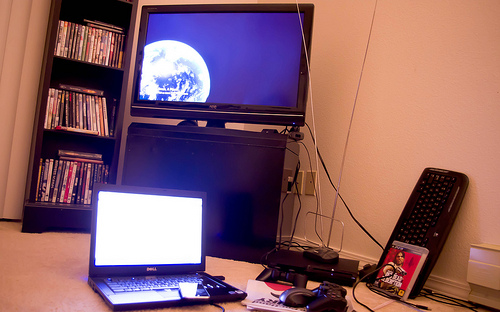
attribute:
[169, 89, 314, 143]
stand — black, television stand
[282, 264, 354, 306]
controllers — black 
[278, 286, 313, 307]
mouse — black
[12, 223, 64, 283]
floor — open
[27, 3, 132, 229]
bookcase — black 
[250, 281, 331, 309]
mouse — black, grey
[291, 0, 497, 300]
wall — white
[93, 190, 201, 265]
screen — bright white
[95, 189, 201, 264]
lit screen — bright white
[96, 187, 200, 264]
white screen — bright white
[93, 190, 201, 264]
bright screen — bright white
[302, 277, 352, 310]
game controller — wireless, video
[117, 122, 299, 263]
stand — black, rectangular, tv stand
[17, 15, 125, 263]
shelves — black, wooden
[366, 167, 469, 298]
keyboard — black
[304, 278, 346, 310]
play station — playstation controller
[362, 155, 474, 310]
keyboard — black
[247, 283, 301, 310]
remote — silver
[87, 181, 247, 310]
laptop — black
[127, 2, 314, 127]
tv — rectangular, large, black, flat screen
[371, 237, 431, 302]
movie — black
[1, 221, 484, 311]
carpet — off white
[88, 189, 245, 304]
laptop — black, dell, computer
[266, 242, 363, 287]
system — black, video game system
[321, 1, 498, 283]
walls — off white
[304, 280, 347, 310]
controller — black